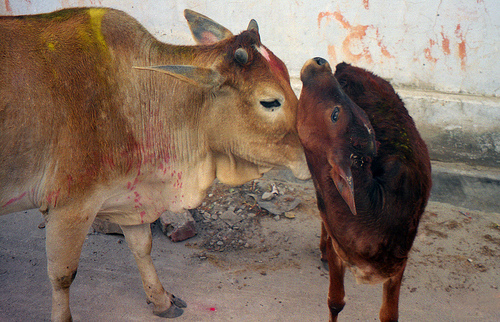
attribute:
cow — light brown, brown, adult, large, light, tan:
[0, 6, 312, 320]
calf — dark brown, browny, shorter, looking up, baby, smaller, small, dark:
[296, 56, 434, 320]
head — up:
[295, 54, 379, 181]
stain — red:
[258, 46, 284, 80]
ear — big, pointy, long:
[328, 153, 359, 218]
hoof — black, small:
[326, 299, 347, 318]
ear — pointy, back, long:
[182, 7, 235, 45]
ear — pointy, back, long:
[132, 63, 223, 88]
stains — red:
[4, 107, 186, 225]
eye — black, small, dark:
[330, 104, 341, 123]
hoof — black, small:
[145, 294, 189, 317]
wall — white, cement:
[0, 1, 499, 214]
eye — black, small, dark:
[258, 100, 282, 111]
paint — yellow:
[38, 6, 114, 79]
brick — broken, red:
[157, 206, 198, 243]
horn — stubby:
[247, 18, 259, 32]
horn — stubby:
[233, 47, 252, 64]